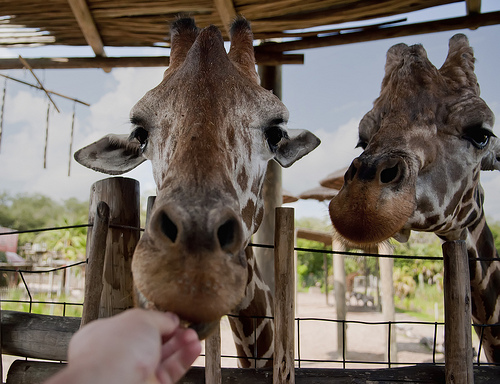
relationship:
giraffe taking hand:
[76, 15, 312, 377] [28, 305, 212, 382]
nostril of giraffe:
[216, 215, 243, 257] [76, 15, 312, 377]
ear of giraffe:
[72, 132, 147, 175] [76, 15, 312, 377]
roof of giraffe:
[0, 0, 500, 75] [325, 31, 499, 368]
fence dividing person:
[2, 219, 495, 382] [29, 305, 201, 382]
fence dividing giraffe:
[2, 219, 495, 382] [325, 31, 499, 368]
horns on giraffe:
[157, 15, 264, 83] [76, 15, 312, 377]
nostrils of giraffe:
[214, 219, 243, 257] [80, 17, 292, 382]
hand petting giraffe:
[67, 307, 202, 383] [78, 8, 329, 338]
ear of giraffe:
[69, 123, 157, 183] [95, 10, 310, 382]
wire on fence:
[340, 316, 353, 371] [295, 310, 458, 368]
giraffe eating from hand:
[76, 15, 312, 377] [67, 291, 203, 382]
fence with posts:
[2, 173, 499, 383] [62, 146, 475, 377]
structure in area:
[275, 198, 410, 371] [12, 52, 479, 365]